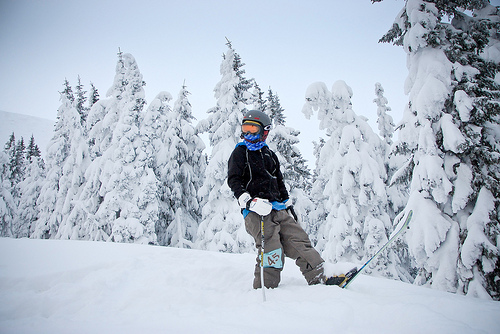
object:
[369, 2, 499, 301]
tree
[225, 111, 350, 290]
man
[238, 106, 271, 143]
helmet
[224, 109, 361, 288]
person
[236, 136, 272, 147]
neck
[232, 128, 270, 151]
scarf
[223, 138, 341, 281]
jacket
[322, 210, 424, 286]
skis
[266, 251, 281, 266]
number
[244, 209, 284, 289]
leg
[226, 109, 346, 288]
skier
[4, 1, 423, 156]
sky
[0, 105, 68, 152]
mountain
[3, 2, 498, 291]
trees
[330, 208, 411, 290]
ski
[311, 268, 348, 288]
foot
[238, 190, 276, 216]
glove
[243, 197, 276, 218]
hand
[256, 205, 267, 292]
ski pole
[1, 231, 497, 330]
ground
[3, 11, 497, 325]
snow